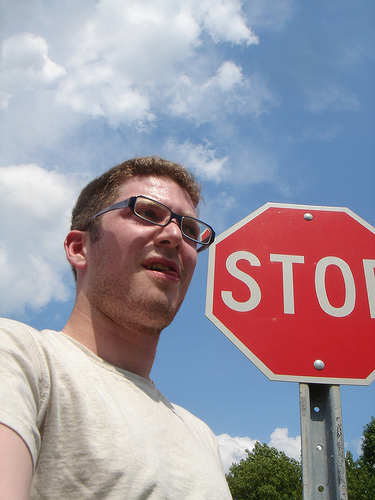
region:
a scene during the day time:
[22, 9, 331, 471]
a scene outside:
[22, 15, 368, 466]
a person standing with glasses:
[2, 136, 244, 481]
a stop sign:
[189, 180, 368, 480]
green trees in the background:
[212, 412, 372, 497]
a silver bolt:
[308, 346, 325, 375]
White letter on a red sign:
[217, 240, 256, 334]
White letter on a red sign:
[266, 243, 299, 338]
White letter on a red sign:
[308, 238, 351, 339]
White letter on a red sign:
[354, 252, 372, 315]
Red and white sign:
[213, 175, 354, 415]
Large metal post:
[288, 380, 350, 490]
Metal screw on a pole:
[308, 349, 328, 377]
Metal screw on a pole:
[296, 205, 317, 222]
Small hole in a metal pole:
[308, 401, 326, 416]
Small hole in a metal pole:
[314, 437, 327, 455]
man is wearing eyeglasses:
[55, 143, 223, 363]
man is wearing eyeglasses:
[64, 142, 211, 361]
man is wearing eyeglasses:
[70, 131, 207, 342]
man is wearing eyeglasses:
[53, 146, 213, 331]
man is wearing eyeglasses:
[73, 143, 197, 353]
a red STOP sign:
[190, 180, 374, 433]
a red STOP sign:
[195, 167, 371, 418]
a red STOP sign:
[199, 185, 372, 371]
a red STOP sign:
[186, 158, 373, 423]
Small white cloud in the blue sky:
[302, 60, 355, 159]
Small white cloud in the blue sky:
[267, 420, 299, 467]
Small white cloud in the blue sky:
[212, 423, 254, 472]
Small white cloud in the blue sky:
[7, 252, 56, 329]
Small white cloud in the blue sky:
[21, 26, 84, 102]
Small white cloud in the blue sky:
[8, 31, 50, 81]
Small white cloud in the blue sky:
[79, 44, 152, 119]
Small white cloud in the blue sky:
[45, 13, 182, 89]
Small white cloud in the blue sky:
[186, 114, 246, 194]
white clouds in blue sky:
[1, 1, 373, 472]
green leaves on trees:
[227, 419, 373, 498]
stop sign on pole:
[204, 201, 371, 498]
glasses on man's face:
[64, 157, 214, 333]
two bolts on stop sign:
[303, 211, 323, 371]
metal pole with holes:
[301, 384, 347, 498]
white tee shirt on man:
[1, 316, 232, 498]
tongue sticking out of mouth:
[142, 258, 182, 277]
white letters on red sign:
[221, 249, 374, 315]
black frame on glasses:
[83, 195, 214, 254]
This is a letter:
[215, 243, 265, 320]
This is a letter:
[265, 248, 312, 321]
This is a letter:
[306, 247, 361, 330]